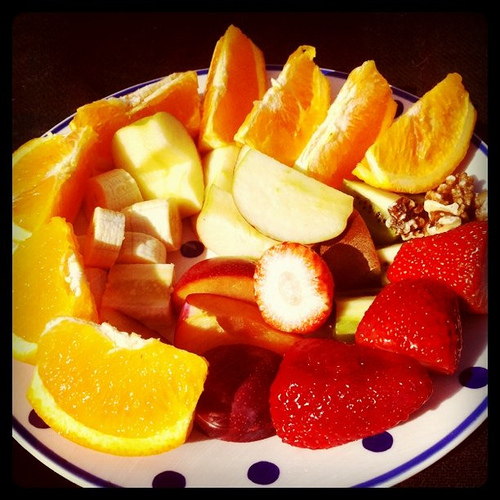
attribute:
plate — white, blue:
[13, 54, 494, 490]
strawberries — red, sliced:
[248, 218, 488, 459]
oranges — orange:
[13, 127, 213, 468]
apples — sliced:
[112, 100, 368, 272]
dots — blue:
[242, 453, 282, 489]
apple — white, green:
[228, 140, 362, 252]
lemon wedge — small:
[29, 316, 209, 456]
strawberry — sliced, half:
[269, 339, 432, 449]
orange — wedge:
[194, 25, 266, 151]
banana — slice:
[80, 205, 124, 269]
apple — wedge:
[230, 145, 359, 246]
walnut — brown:
[423, 170, 483, 227]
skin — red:
[193, 343, 279, 440]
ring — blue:
[12, 67, 498, 487]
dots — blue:
[27, 364, 485, 487]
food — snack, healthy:
[12, 20, 483, 454]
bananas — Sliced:
[82, 170, 182, 266]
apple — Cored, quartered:
[112, 112, 354, 264]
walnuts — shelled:
[386, 170, 481, 243]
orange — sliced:
[26, 314, 208, 458]